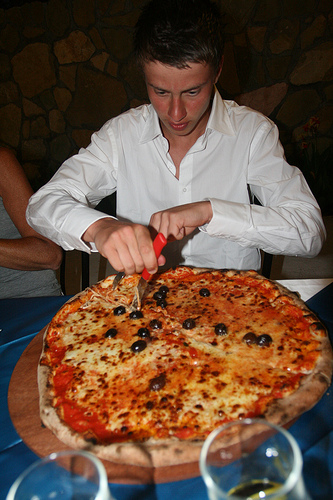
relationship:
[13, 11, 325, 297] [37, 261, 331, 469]
man cutting up pizza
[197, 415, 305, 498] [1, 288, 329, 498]
glass on tablecloth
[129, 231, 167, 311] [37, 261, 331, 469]
knife cutting into pizza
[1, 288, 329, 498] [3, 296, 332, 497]
tablecloth on table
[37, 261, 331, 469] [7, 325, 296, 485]
pizza on board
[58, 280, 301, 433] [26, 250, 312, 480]
cheese on piza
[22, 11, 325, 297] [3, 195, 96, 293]
man sitting on chair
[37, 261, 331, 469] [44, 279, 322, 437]
pizza has cheese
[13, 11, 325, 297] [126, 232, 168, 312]
man cutting with a knife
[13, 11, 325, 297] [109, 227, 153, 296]
man cutting with a fork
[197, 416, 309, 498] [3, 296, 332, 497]
glass sit on table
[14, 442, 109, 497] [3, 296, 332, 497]
glass sit on table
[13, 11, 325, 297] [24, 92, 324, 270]
man wearing a shirt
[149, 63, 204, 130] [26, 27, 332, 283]
face of man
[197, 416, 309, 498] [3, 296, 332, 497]
glass on table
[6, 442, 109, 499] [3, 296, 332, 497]
glass on table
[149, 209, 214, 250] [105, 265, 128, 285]
left hand holding fork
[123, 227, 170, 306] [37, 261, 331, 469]
knife cutting pizza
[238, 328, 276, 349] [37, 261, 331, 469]
olives on pizza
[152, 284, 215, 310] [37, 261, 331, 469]
olives on pizza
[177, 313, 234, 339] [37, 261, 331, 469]
olives on pizza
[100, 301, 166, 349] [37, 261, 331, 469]
olives on pizza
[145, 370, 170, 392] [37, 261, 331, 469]
olives on pizza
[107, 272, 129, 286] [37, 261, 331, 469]
fork holding pizza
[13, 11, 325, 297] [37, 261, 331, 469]
man cutting pizza